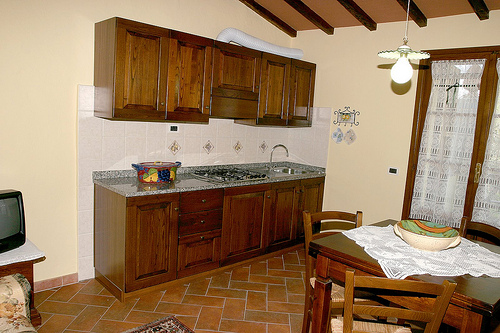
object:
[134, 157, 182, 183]
pot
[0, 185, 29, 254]
small tv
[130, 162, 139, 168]
handle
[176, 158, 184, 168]
handle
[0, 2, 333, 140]
pictures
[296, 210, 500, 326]
table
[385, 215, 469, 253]
bowl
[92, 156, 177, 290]
cabinets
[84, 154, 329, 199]
countertop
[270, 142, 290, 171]
faucet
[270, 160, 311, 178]
sink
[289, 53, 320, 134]
cabinets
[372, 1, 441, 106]
fixture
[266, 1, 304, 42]
rafters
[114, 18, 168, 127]
door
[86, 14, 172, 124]
cabinet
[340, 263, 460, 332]
cloth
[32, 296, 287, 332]
floor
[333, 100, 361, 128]
items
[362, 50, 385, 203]
wall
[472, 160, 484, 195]
knob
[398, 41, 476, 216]
door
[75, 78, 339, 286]
backsplash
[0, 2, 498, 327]
kitchen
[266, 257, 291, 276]
tile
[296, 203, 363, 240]
chairs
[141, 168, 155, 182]
fruit decorations